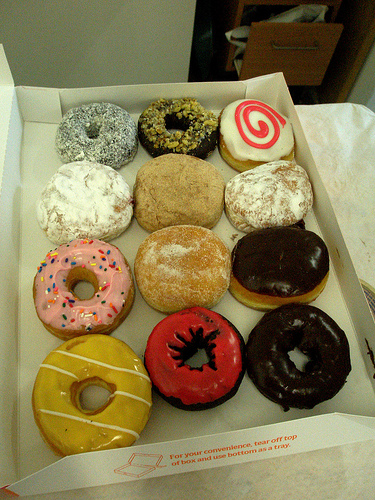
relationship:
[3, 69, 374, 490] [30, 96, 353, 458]
box has donuts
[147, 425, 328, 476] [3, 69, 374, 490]
instructions on box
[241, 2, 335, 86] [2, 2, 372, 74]
drawer in back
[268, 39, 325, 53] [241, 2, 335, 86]
handle on drawer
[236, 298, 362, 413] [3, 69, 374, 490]
donut in box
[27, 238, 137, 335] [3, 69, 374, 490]
donut in box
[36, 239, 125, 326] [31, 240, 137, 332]
sprinkles on frosting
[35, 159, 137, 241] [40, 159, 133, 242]
donut has powdered sugar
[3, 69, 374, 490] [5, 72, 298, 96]
box has edge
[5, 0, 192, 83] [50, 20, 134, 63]
surface has part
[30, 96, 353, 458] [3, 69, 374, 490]
donuts in box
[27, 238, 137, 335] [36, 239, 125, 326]
donut has sprinkles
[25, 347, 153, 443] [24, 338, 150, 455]
lines are on donut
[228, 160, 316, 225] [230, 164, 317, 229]
donut has powder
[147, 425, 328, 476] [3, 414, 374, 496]
writing on side of cardboard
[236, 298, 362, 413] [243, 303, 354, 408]
donut has frosting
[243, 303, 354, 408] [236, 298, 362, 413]
frosting on donut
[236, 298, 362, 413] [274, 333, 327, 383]
donut has hole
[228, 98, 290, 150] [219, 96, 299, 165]
swirl on donut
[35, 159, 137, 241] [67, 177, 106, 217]
donut has no hole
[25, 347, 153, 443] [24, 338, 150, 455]
stripes are on donut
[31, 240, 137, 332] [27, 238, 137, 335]
frosting on doughnut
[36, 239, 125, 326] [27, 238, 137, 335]
sprinkles are on doughnut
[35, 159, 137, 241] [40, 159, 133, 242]
doughnut has powdered sugar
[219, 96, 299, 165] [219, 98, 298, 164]
doughnut has frosting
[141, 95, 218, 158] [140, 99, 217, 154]
donut has nuts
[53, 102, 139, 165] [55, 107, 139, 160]
doughnut has powdered sugar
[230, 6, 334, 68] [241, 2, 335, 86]
bag in drawer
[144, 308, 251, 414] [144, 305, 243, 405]
this is some cream